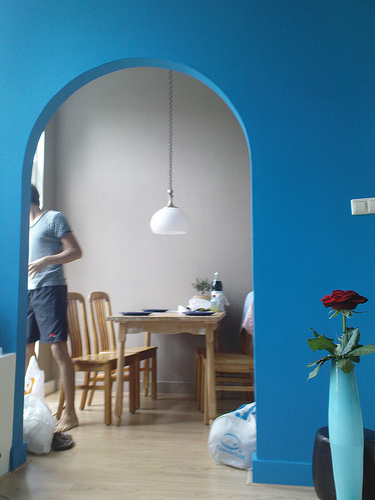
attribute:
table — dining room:
[100, 312, 223, 429]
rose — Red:
[312, 292, 357, 381]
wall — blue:
[3, 3, 365, 494]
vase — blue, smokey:
[321, 344, 374, 496]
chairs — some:
[64, 288, 149, 420]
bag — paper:
[206, 386, 263, 469]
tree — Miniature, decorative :
[178, 267, 220, 299]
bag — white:
[22, 354, 46, 399]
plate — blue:
[114, 307, 155, 319]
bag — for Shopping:
[21, 363, 49, 439]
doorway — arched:
[21, 53, 255, 484]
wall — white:
[44, 68, 255, 394]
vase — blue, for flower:
[321, 356, 372, 492]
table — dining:
[103, 296, 226, 416]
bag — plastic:
[24, 351, 59, 456]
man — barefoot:
[19, 182, 83, 436]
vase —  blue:
[326, 361, 363, 497]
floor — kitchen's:
[45, 393, 210, 469]